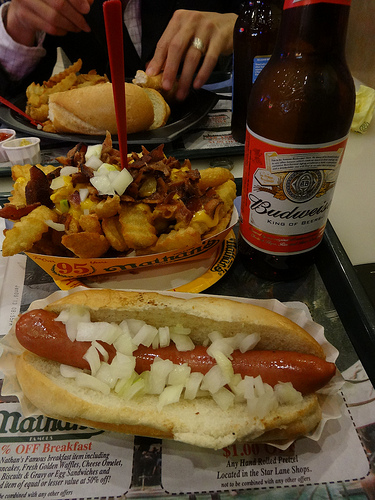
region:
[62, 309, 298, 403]
onions on top of hot dog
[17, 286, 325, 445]
a full hot dog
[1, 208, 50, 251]
a piece of crinkle cut fry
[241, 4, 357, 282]
a bottle of budweiser beer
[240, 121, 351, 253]
the beer label is red and white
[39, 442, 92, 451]
the word "breakfast" in red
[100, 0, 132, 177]
a red fork in fries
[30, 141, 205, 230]
various toppings on top of french fries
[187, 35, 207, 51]
a ring on the ring finger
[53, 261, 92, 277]
the number 95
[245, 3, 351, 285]
glass bottle of beer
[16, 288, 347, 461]
hotdog with onions in it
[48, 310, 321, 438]
diced oninions laying on the meat and bread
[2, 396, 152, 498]
coupon for a percentage off a breakfast meal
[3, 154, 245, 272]
food piled in a paper tray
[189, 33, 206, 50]
ring wrapped around the finger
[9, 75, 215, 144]
food on a plate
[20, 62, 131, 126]
pile of golden fries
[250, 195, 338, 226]
black cursive writing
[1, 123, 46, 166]
two paper cups filled with sauce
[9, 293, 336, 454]
a hotdog with onions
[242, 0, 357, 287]
a dark brown bottle labeled, "Budweiser"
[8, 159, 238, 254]
a pile of laoded french fries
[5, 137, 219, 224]
crunchy bacon pieces on top of fries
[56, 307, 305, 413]
a pile of chopped onions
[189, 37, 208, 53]
a gold ring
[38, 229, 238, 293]
a yellow paper plate with the brand "Nathan's" printed on edge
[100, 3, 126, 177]
a plastic red utensil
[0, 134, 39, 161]
small paper ramekin of mustard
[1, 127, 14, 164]
a small paper ramekin of ketchup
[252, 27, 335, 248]
brown bottle of beer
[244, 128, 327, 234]
red and white label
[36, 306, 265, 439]
white onions on hot dog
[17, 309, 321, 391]
brown hot dog on bun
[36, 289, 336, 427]
dark brown toasted bun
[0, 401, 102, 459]
green and white company name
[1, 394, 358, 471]
placemat with coupons under hot dog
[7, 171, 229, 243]
brown french fries in paper basket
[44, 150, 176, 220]
onions on french fries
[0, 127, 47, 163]
souffle cups with mustard and ketchup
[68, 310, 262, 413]
onions on the hot dog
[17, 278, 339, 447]
hot dog is in a bun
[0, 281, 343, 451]
bun is in a paper dish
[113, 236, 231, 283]
Nathan's written on side of french fries container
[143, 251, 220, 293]
french fries container is in a bowl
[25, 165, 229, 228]
bacon on top of the french fries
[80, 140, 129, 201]
onions on top of the bacon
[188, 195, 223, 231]
cheese on the french fries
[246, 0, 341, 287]
beer bottle on the food tray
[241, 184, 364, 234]
Budweiser is on the label of the beer